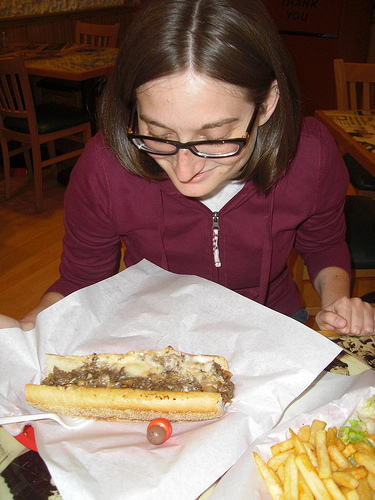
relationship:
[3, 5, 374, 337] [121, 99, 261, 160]
woman wear glasses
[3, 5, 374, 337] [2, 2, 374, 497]
woman in photo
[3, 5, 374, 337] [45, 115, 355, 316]
woman wearing sweater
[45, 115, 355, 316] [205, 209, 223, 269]
sweater has zipper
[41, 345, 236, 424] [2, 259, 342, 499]
chhesesteak on paper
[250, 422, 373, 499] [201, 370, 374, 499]
fries on paper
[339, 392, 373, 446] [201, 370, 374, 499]
lettuce on paper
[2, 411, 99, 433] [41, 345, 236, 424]
fork under chhesesteak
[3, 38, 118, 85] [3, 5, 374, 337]
table behind woman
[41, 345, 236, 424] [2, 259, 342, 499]
chhesesteak on top of paper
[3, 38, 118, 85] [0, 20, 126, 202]
table between chairs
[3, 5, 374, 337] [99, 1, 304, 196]
woman has hair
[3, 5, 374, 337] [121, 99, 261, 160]
woman wearing glasses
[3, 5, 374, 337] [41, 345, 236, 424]
woman looking chhesesteak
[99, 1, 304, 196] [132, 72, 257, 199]
hair around face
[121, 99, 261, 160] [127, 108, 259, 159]
glasses have frames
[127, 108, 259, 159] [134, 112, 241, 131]
frames below eyebrows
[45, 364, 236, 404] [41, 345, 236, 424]
beef on chhesesteak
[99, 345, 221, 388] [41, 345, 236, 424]
cheese on chhesesteak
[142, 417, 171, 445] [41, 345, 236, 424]
object next to chhesesteak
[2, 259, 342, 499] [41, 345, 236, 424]
paper under chhesesteak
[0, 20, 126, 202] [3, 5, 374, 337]
chairs behind woman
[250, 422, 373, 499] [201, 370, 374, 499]
fries on top of paper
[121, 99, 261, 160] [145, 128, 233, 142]
glasses covering eyes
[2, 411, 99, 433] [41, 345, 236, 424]
fork next to chhesesteak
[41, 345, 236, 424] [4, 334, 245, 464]
chhesesteak on top of plate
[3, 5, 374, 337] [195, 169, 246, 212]
woman wearing t-shirt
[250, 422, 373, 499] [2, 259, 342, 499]
fries on top of paper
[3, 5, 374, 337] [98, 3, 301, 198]
woman has head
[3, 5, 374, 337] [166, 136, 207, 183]
woman has nose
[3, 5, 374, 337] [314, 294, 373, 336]
woman has hand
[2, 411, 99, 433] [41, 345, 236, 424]
fork under cheesesteak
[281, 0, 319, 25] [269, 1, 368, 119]
sign on door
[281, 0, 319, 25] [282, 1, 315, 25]
sign says thank you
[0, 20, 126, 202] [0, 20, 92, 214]
chairs has chairs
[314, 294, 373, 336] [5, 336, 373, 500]
hand sitting on table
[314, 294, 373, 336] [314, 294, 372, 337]
hand in hand